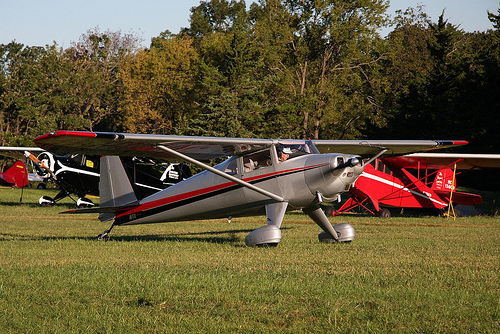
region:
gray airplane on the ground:
[33, 130, 466, 247]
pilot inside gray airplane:
[279, 145, 291, 159]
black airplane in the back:
[1, 145, 192, 207]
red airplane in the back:
[331, 152, 498, 219]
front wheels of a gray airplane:
[244, 222, 354, 246]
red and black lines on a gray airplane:
[113, 162, 330, 224]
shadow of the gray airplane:
[1, 227, 286, 241]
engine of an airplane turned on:
[321, 148, 380, 175]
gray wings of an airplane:
[33, 130, 465, 158]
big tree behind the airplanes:
[233, 0, 391, 138]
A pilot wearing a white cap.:
[274, 125, 319, 167]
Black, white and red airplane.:
[47, 125, 464, 246]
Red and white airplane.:
[359, 158, 484, 223]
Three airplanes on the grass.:
[10, 112, 494, 272]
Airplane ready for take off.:
[33, 127, 470, 243]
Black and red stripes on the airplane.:
[109, 163, 339, 226]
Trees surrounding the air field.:
[6, 0, 498, 130]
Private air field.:
[5, 26, 497, 331]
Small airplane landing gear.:
[238, 195, 363, 248]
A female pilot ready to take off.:
[275, 138, 317, 160]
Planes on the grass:
[0, 118, 491, 249]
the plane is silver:
[33, 131, 475, 237]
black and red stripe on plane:
[106, 159, 328, 225]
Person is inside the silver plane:
[269, 141, 305, 168]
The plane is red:
[339, 154, 484, 215]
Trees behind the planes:
[3, 7, 493, 181]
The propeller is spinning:
[313, 146, 383, 192]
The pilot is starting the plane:
[34, 110, 470, 249]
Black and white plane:
[6, 134, 203, 216]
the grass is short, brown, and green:
[4, 169, 488, 330]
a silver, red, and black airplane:
[32, 123, 475, 269]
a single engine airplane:
[28, 98, 474, 274]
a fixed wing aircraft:
[30, 100, 484, 258]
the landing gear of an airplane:
[243, 202, 291, 254]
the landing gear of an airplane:
[305, 205, 363, 248]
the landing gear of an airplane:
[89, 218, 115, 247]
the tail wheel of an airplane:
[92, 219, 120, 237]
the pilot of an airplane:
[276, 143, 291, 162]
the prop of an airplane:
[308, 141, 379, 191]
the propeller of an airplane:
[318, 136, 375, 183]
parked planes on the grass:
[19, 35, 498, 283]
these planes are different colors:
[18, 102, 488, 263]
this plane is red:
[354, 132, 478, 226]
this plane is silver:
[57, 97, 377, 260]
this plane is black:
[27, 145, 200, 199]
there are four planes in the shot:
[4, 101, 481, 244]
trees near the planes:
[9, 34, 462, 119]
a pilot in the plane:
[259, 137, 298, 166]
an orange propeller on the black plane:
[18, 147, 62, 179]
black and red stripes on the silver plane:
[114, 172, 327, 225]